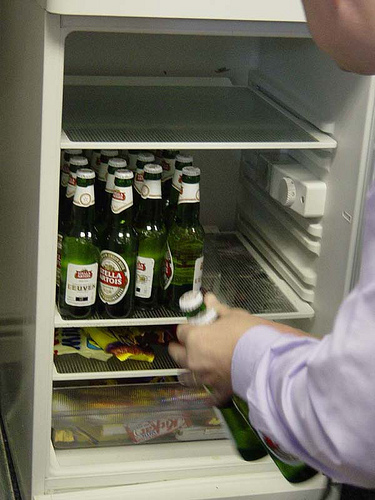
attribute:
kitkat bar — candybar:
[126, 413, 184, 441]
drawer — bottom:
[51, 383, 234, 443]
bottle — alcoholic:
[131, 162, 167, 309]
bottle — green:
[172, 165, 213, 315]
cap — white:
[177, 161, 204, 181]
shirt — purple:
[255, 281, 373, 448]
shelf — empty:
[58, 72, 345, 152]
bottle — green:
[136, 162, 168, 314]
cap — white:
[142, 163, 163, 175]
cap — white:
[113, 168, 134, 181]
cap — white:
[73, 166, 98, 181]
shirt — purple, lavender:
[229, 176, 373, 491]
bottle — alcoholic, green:
[157, 163, 204, 313]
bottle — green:
[52, 165, 103, 318]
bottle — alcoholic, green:
[95, 168, 141, 318]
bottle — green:
[133, 160, 165, 307]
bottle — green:
[159, 165, 208, 315]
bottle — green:
[166, 151, 192, 228]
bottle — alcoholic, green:
[56, 165, 105, 318]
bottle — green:
[97, 165, 137, 315]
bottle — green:
[127, 163, 171, 306]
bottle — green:
[164, 151, 189, 216]